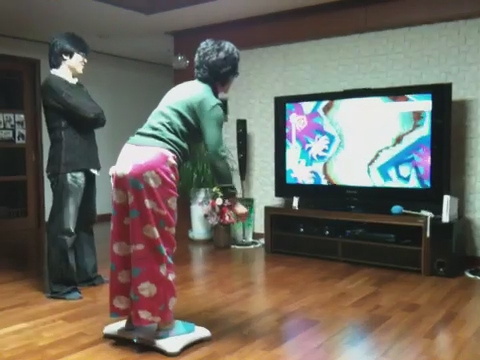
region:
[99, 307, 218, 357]
This is a Wii Balance Board.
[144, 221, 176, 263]
White and blue clouds on a pink background.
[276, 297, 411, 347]
A wooden tile floor.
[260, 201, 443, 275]
A full entertainment center.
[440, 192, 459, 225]
A Nintendo Wii Console.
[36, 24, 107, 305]
A man standing in the room.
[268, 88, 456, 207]
A television with a large screen.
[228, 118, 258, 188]
A black stand in the corner.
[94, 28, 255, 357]
An elderly woman playing a video game.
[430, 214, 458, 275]
A large, black speaker.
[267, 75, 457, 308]
television sitting on tv stand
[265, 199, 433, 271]
a wooden tv stand with glass fronts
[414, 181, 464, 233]
A Wii game system sitting next to tv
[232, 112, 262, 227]
A slim speaker sitting next to the tv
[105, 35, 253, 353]
Older lady playing the Wii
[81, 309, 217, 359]
The Wii game pad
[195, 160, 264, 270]
A collection of house plants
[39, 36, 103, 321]
A person laughing and watching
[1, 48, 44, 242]
a door leading to another room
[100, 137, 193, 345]
an older woman wearing sleep pants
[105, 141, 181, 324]
pink pants with white and blue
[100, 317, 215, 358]
wii controller on the floor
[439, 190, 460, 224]
white wii console on the tv stand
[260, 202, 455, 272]
brown tv stand under the tv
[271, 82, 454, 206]
black television on the tv stand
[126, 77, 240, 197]
green long sleeve shirt on the woman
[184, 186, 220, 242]
white vase for the plant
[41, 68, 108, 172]
man wearing a black long sleeve shirt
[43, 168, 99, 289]
black pants on the man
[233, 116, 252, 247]
black standing speaker next to the television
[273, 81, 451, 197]
large flat screen TV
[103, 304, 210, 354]
Wii pad to stand on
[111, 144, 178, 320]
pink pants with flowers on them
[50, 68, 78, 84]
white collar on man's shirt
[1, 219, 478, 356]
brown hard wood floors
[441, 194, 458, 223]
Wii console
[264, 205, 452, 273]
rectangle TV table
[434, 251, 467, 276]
speaker on the ground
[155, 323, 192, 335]
blue sock on her foot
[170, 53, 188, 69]
light fixture on the wall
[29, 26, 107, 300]
A man in a black shirt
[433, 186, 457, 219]
A white 'Nintendo Wii'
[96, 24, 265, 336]
A person in a green shirt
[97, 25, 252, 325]
A person wearing red pants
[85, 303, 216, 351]
A 'Nintendo Wii Fit'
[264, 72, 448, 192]
A large flat screen tv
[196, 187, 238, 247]
A potted plant on the floor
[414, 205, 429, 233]
A white 'Wii Remote'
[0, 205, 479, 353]
A hard wood floor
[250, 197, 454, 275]
A wide wooden shelf